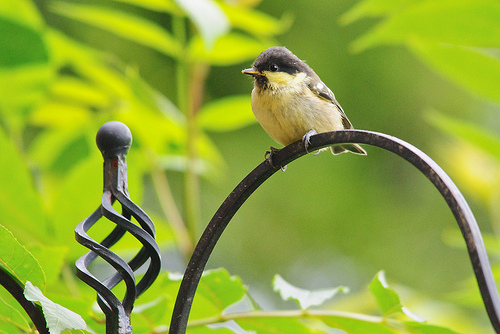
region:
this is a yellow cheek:
[256, 64, 296, 88]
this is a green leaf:
[253, 258, 361, 313]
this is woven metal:
[74, 192, 171, 309]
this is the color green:
[317, 180, 344, 220]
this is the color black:
[105, 253, 116, 261]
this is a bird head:
[232, 34, 312, 99]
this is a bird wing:
[306, 75, 351, 130]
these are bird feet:
[261, 125, 326, 178]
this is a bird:
[226, 17, 376, 202]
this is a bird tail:
[320, 116, 367, 161]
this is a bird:
[241, 50, 362, 162]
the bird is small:
[238, 45, 367, 167]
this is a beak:
[242, 68, 263, 77]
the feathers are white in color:
[266, 91, 328, 115]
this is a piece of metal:
[100, 128, 140, 325]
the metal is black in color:
[101, 135, 122, 184]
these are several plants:
[25, 0, 175, 313]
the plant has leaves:
[14, 236, 43, 286]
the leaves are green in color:
[24, 203, 54, 255]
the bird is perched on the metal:
[217, 44, 381, 166]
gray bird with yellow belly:
[219, 38, 386, 171]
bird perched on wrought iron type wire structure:
[218, 44, 375, 168]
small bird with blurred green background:
[178, 30, 447, 264]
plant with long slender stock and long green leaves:
[136, 0, 233, 195]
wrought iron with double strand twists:
[60, 116, 168, 325]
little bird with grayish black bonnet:
[225, 35, 390, 178]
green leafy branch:
[223, 268, 448, 332]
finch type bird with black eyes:
[234, 39, 306, 99]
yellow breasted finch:
[236, 35, 373, 172]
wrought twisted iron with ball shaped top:
[61, 105, 163, 332]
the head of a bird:
[238, 40, 297, 86]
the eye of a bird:
[264, 55, 284, 76]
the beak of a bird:
[237, 61, 268, 79]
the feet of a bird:
[258, 120, 328, 175]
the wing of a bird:
[305, 71, 356, 125]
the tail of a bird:
[323, 130, 376, 166]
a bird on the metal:
[235, 41, 375, 176]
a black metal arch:
[161, 124, 493, 331]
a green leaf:
[18, 275, 89, 331]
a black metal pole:
[71, 110, 166, 332]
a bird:
[213, 27, 380, 251]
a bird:
[249, 84, 381, 219]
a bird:
[239, 39, 339, 169]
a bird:
[211, 53, 306, 175]